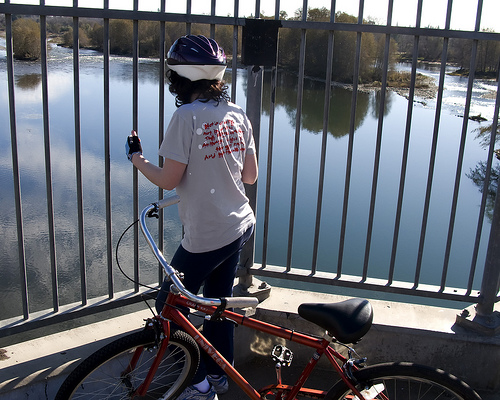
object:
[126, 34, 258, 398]
person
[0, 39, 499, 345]
water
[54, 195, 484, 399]
bicycle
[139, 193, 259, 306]
handlebars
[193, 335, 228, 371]
writing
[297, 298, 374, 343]
seat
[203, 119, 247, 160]
writing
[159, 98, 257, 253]
shirt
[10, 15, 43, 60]
tree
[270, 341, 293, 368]
petal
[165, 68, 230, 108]
hair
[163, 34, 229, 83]
helmet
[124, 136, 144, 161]
glove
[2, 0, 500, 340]
fence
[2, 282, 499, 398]
concrete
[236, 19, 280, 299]
pole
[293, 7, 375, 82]
trees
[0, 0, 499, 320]
background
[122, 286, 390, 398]
frame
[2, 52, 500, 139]
reflection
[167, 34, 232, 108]
head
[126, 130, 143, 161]
hand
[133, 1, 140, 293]
rail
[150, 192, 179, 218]
handle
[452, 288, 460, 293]
bolt